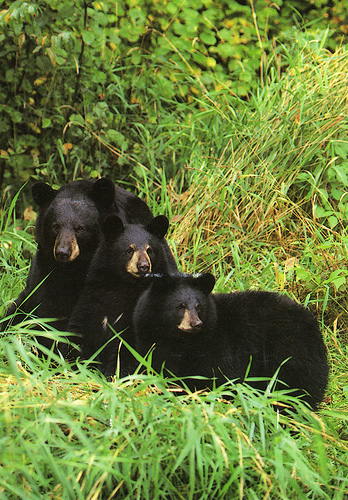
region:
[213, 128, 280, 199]
part of some grass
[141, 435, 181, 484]
part of a grass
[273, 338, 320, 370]
stomach of a bear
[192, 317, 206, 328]
nose of a bear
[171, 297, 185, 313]
eye of a bear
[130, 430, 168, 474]
part of a grass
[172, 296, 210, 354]
face of a bear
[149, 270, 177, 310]
part of an ear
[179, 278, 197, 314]
head of a bear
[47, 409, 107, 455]
part of a grass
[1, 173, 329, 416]
three black bears next to each other standing in shrubs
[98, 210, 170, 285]
face of black bear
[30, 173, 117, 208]
two ears of black bear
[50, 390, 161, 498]
patch of tall green grass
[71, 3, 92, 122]
tree leaves and brown stem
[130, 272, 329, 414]
one small black bear standing in tall grass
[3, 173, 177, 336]
one large adult black bear standing in tall gras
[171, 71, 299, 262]
patch of tall yellowed green foilage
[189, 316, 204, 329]
nose of black bear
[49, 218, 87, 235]
black bear eyes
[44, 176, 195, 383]
these are three bears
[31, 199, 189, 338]
the bears are black in color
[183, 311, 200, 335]
this is the nose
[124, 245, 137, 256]
the eye is open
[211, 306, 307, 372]
the bear is fury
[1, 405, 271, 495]
this is the grass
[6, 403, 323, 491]
the grass are green in color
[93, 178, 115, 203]
this is the ear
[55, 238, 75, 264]
the nose is long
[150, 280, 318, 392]
the bear is sitted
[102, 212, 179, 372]
The bear in the middle.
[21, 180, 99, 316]
The bear on the left side.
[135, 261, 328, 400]
The bear on the right side.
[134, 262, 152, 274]
The nose of the bear in the middle.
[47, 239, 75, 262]
The nose of the bear on the left side.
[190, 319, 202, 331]
The nose of the bear on the right side.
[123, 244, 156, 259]
The eyes of the bear in the middle.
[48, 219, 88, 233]
The eyes of the bear on the left side.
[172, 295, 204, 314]
The eyes of the bear on the right side.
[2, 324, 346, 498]
The grass blades in front of where the three bears are located.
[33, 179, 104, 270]
face of black bear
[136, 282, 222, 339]
face of black bear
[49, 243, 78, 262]
black nose of black bear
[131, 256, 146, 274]
black nose of black bear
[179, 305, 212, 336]
black nose of black bear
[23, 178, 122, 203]
ears of a black bear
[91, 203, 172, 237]
ears of a black bear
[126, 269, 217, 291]
ears of a black bear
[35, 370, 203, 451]
green grass